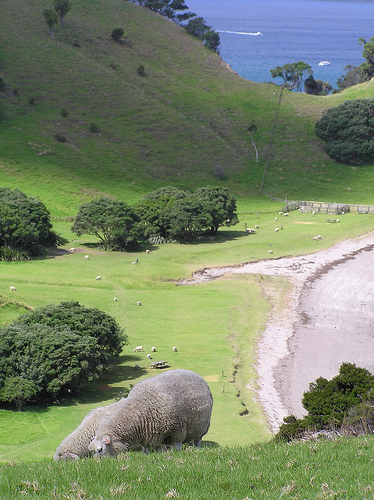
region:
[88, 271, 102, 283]
sheep in the pasteur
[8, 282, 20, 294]
sheep in the pasteur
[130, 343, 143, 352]
sheep in the pasteur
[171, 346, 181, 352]
sheep in the pasteur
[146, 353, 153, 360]
sheep in the pasteur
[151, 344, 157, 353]
sheep in the pasteur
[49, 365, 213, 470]
sheep in the pasteur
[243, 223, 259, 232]
sheep in the pasteur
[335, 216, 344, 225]
sheep in the pasteur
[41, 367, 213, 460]
Sheep grazing on hillside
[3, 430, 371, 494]
Green grass on top of hill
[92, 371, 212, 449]
Fleece coat on sheep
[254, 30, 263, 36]
Power boat moving through the water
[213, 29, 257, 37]
Wake caused by power boat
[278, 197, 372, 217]
Sheep tending area in field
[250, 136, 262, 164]
Wooden log in field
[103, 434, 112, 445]
Identification tag in sheep's ear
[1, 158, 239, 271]
green trees in field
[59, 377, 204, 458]
two sheep in fore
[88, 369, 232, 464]
sheep have grey wool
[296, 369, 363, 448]
green trees over hill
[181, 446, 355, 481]
green grass near sheep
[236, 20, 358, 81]
water is dark blue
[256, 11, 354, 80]
two boats on water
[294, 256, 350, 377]
grey sand near fields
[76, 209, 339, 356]
many sheep in valley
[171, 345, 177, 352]
a white sheep grazing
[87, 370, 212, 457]
a white sheep grazing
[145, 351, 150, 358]
a white sheep grazing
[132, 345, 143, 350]
a white sheep grazing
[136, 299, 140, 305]
a white sheep grazing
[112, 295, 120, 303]
a white sheep grazing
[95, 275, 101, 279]
a white sheep grazing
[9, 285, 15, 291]
a white sheep grazing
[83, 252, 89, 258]
a white sheep grazing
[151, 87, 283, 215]
a field of green grass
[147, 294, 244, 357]
a field of short grass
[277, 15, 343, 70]
a body of water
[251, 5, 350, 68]
a body of blue water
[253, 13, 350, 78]
a body of water that is blue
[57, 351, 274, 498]
sheep standing outside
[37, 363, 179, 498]
sheep eatting outside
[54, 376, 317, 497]
sheep in a field